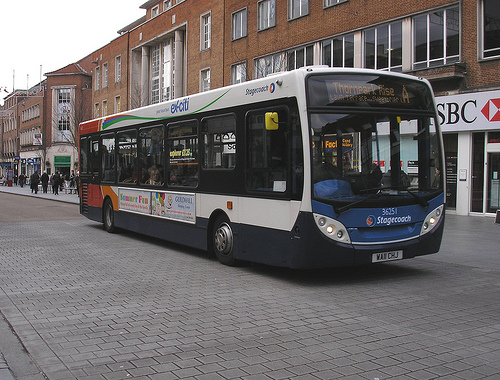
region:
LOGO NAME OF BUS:
[364, 213, 418, 230]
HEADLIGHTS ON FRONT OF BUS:
[310, 210, 353, 245]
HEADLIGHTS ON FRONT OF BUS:
[413, 203, 447, 240]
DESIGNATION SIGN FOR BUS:
[306, 74, 432, 112]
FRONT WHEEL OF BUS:
[200, 207, 244, 265]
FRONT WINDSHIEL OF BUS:
[306, 111, 393, 202]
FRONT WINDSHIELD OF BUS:
[393, 105, 448, 201]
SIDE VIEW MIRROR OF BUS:
[261, 110, 286, 135]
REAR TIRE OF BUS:
[95, 195, 120, 227]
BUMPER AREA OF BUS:
[316, 237, 458, 267]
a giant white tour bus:
[70, 68, 471, 284]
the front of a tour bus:
[293, 66, 455, 273]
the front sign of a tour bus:
[315, 66, 417, 108]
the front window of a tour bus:
[296, 119, 424, 194]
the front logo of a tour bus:
[362, 214, 411, 231]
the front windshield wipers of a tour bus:
[306, 152, 453, 209]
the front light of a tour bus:
[311, 220, 373, 241]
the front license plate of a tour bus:
[351, 248, 411, 267]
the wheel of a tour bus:
[198, 212, 238, 263]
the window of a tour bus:
[145, 124, 222, 184]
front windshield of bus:
[310, 82, 437, 237]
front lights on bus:
[310, 212, 350, 244]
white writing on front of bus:
[370, 212, 420, 237]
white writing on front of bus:
[415, 206, 440, 236]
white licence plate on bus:
[371, 241, 408, 261]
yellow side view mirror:
[265, 109, 282, 127]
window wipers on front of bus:
[307, 182, 382, 217]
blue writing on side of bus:
[168, 96, 192, 114]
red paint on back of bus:
[81, 119, 105, 216]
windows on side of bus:
[70, 115, 255, 165]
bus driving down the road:
[61, 92, 405, 322]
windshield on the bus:
[327, 107, 452, 216]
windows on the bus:
[104, 121, 239, 211]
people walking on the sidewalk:
[16, 150, 86, 227]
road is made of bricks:
[44, 228, 195, 376]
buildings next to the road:
[101, 24, 496, 216]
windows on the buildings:
[316, 10, 465, 80]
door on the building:
[462, 132, 497, 217]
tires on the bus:
[194, 214, 250, 268]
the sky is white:
[23, 16, 84, 58]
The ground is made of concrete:
[67, 242, 207, 361]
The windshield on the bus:
[305, 109, 445, 201]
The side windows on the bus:
[71, 101, 305, 210]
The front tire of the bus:
[207, 207, 240, 267]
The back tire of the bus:
[96, 191, 121, 233]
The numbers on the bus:
[377, 200, 402, 217]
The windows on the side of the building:
[88, 53, 124, 120]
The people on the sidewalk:
[1, 162, 83, 198]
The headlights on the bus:
[324, 214, 440, 236]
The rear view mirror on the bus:
[258, 106, 290, 133]